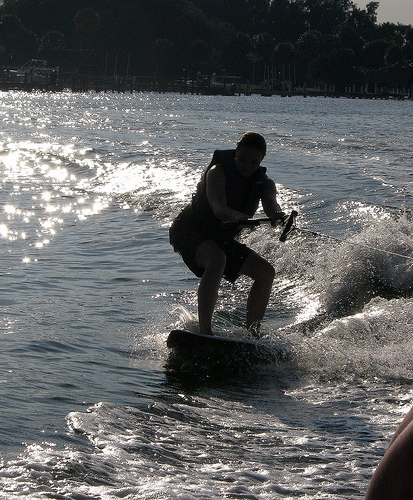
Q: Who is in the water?
A: A man.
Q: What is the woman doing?
A: Skiing.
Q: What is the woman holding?
A: A ski rope.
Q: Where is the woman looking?
A: Down.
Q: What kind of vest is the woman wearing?
A: A float coat.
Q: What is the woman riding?
A: A water board.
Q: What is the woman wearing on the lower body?
A: Shorts.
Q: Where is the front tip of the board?
A: Above the water.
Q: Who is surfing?
A: The woman.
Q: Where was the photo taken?
A: Outdoors somewhere.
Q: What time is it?
A: Afternoon.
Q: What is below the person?
A: Water.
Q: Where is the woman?
A: On water.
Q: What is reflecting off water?
A: Sunlight.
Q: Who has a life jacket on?
A: The woman.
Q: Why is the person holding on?
A: To get dragged.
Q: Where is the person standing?
A: ON a wakeboard.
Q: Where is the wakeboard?
A: In the water.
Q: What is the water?
A: A lake.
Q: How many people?
A: 1.